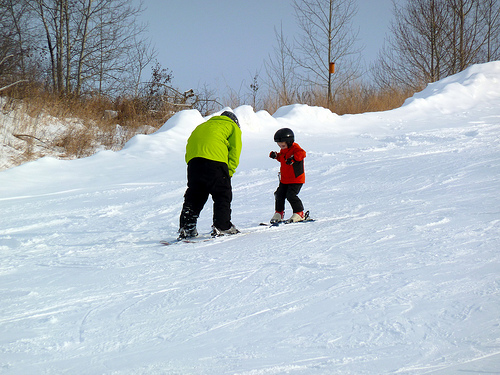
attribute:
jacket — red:
[273, 142, 306, 184]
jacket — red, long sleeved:
[271, 141, 311, 183]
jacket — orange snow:
[265, 141, 307, 186]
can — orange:
[330, 61, 335, 73]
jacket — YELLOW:
[171, 110, 261, 175]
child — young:
[261, 122, 315, 229]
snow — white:
[381, 165, 433, 230]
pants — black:
[270, 178, 302, 214]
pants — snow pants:
[177, 162, 247, 238]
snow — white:
[329, 171, 478, 324]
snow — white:
[0, 61, 500, 373]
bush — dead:
[53, 125, 99, 160]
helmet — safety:
[270, 116, 312, 143]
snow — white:
[215, 272, 277, 334]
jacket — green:
[163, 120, 265, 164]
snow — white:
[13, 228, 107, 265]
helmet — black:
[274, 123, 300, 148]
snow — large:
[335, 180, 476, 317]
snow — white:
[335, 179, 442, 322]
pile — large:
[401, 58, 496, 113]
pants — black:
[176, 154, 233, 233]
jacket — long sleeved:
[184, 114, 242, 174]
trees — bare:
[0, 0, 498, 111]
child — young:
[269, 124, 309, 224]